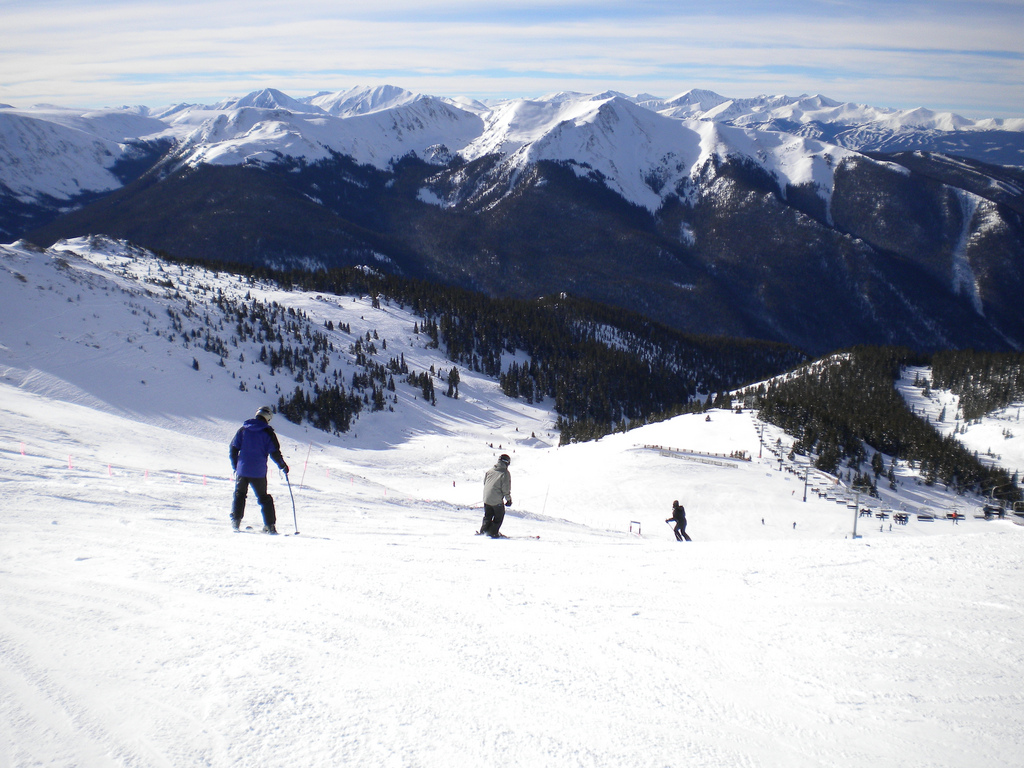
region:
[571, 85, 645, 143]
the pick of a mountain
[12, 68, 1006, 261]
mountain is covered with snow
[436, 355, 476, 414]
tree on a hill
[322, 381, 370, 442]
tree on a hill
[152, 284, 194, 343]
tree on a hill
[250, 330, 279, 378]
the tree on a hill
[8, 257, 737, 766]
snow on a hill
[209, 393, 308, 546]
the man wears blue coat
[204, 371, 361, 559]
man going down the hill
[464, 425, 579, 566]
man going down the hill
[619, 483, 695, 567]
man going down the hill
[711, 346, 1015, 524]
trees on a hill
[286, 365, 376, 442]
the trees on the hill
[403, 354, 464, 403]
the trees on the hill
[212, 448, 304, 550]
the legs of a man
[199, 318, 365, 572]
a man on skis in the snow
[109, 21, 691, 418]
snow on top of mountains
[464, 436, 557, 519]
a man wearing a coat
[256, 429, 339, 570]
a man holding a ski stick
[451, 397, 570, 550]
a man wearing pants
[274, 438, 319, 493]
the hand of a man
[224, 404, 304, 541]
A person wearing a puffy blue jacket.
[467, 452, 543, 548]
A person standing on a snow covered hill.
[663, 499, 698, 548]
A person riding to the left on a ski slope.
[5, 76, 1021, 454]
A mountain range covered in snow.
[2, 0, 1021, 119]
A hazy fog filled sky.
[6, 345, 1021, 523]
A tree covered snow filled hill.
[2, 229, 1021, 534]
A small mountain range covered in snow and trees.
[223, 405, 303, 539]
A man wearing ski clothing.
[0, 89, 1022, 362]
A mountain range covered in snow and trees.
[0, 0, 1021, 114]
A cloudy blue sky with snow clouds.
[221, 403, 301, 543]
skier wearing big coat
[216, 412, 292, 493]
skiers coat is blue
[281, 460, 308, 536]
skier holding ski pole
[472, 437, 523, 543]
middle man on snowboard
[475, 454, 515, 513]
snowboarder wearing small jacket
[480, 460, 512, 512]
snowboarders jacket is tan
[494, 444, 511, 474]
snowboarder wearing knit cap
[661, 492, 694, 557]
skier skiing down hill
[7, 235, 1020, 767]
snow on hill side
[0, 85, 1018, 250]
snow on cap of mountains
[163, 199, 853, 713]
this is a ski slope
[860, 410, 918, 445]
green leaves on the tree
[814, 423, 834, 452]
green leaves on the tree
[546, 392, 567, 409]
green leaves on the tree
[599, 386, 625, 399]
green leaves on the tree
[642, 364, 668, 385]
green leaves on the tree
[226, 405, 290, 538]
A skier wearing blue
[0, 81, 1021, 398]
Snow capped mountain range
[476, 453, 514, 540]
A skier looking downhill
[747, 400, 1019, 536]
A long ski lift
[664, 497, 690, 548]
A skier wearing dark clothing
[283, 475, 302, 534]
A ski pole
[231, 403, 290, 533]
A skier standing still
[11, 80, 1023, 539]
mountains covered in snow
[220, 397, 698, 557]
people skiing down the mountain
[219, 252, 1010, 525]
trees on the mountain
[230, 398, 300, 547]
man wearing a blue coat